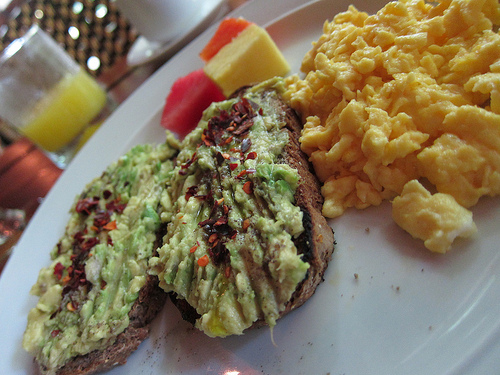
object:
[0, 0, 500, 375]
plate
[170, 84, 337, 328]
bread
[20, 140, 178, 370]
guacamole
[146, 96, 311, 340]
avocado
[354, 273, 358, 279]
crumb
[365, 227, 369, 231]
crumb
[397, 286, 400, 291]
crumb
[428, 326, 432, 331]
crumb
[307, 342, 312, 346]
crumb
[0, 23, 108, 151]
glass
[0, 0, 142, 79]
chair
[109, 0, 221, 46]
cup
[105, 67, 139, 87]
table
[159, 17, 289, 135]
fruit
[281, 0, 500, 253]
eggs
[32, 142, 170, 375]
steak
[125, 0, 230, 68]
saucer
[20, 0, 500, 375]
food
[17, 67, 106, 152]
orange juice